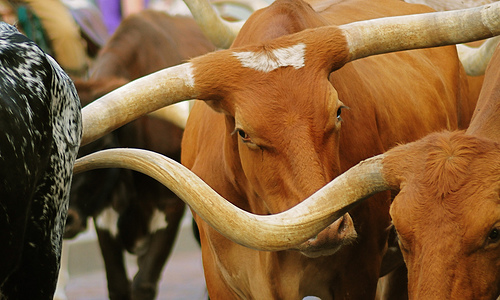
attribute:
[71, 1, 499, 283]
cow — speckled, brown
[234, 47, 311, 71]
spot — white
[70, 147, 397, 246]
horn — beige, curved, curvy, curly, growing, long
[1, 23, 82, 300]
markings — black, white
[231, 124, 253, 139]
eye — black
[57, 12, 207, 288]
cow — brown, dark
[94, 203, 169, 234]
markings — white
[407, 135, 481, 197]
hair — circular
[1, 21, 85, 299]
animal — black, white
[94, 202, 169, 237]
patches — white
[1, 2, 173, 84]
person — watching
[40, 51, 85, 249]
tail — speckled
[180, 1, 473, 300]
bull — large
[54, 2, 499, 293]
cows — brown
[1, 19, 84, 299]
spots — white